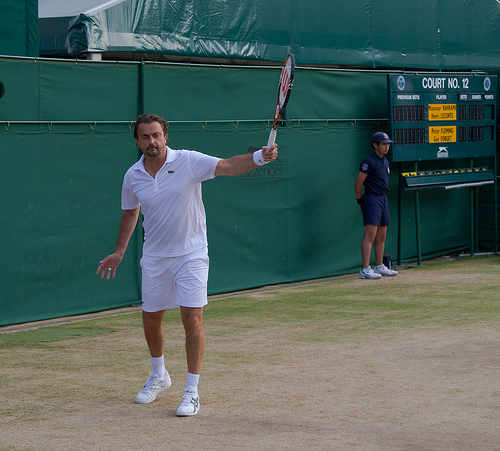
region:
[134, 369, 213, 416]
Man wearing shoes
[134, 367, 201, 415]
Man is wearing shoes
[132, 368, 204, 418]
Man wearing white shoes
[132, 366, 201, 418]
Man is wearing white shoes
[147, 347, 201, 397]
Man wearing socks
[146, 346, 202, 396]
Man is wearing socks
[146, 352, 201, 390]
Man wearing white socks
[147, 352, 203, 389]
Man is wearing white socks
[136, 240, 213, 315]
Man is wearing shorts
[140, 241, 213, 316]
Man is wearing white shorts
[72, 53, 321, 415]
This man is playing tennis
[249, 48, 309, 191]
Man is holding his tennis racket in his left hand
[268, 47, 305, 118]
Tennis racket has a W on it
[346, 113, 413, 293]
Person working the tennis match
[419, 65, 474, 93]
Playing on court no. 12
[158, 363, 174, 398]
Right heel is off of the ground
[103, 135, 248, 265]
Man is wearing a white polo shirt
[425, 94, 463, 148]
Tennis players names on yellow signs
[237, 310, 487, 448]
Dried out brown grass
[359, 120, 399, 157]
Man is wearing a blue hat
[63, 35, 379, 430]
he is warming up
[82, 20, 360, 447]
he is going to play tennis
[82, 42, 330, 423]
he is dressed in all white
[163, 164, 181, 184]
the Lacoste logo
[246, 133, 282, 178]
a white wristband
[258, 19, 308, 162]
his racket is black, red, and white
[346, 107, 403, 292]
a tennis ball boy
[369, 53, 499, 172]
a tennis court score board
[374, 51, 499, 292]
this score board is for court 12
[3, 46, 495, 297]
a green fence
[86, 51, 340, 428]
male tennis player dressed in white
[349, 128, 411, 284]
short man dressed in blue on the sidelines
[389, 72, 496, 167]
green score board with white lettering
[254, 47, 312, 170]
black, red and white tennis racket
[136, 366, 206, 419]
white tennis shoes and socks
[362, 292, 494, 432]
very faded green ground of the tennis court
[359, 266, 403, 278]
white tennis shoes on the man nearby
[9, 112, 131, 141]
green pole along the green wall of the court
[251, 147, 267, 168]
white wrist band on the player's wrist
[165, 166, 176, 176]
small logo on the player's white shirt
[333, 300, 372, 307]
green grass on court.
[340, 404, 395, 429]
brown grass on court.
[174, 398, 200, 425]
tennis shoe on man.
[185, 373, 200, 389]
sock on man's ankle.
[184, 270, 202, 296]
white shorts on man.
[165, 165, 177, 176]
logo on man's shirt.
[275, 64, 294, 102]
head of the racquet.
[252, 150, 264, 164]
band on man's wrist.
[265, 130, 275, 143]
handle of the racquet.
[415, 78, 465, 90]
writing on the scoreboard.